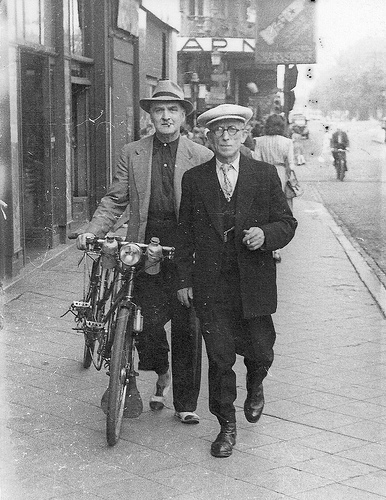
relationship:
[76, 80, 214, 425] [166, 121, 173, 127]
man smoking a cigar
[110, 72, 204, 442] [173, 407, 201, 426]
man wears shoe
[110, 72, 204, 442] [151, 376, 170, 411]
man wears shoe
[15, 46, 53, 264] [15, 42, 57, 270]
door with trim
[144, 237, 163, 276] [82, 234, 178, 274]
bottle on handlebars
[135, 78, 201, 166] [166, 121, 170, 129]
man with cigar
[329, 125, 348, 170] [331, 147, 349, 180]
man riding bicycle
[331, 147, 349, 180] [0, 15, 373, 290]
bicycle in distance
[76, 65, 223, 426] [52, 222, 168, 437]
man holding up bicucle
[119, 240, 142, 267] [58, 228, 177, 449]
headlight on bicycle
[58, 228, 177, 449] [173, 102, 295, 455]
bicycle by man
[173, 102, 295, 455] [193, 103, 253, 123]
man wearing hat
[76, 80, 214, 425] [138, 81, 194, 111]
man wearing hat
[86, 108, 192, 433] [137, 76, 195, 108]
man wearing hat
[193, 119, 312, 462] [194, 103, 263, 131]
man wearing hat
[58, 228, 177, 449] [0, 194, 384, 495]
bicycle on pavement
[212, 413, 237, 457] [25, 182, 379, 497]
boot on pavement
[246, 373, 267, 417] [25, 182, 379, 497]
boot on pavement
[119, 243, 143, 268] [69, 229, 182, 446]
headlight on bicycle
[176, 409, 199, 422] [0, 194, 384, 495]
shoes on pavement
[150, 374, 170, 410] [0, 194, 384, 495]
shoes on pavement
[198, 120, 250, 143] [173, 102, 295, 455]
glasses on man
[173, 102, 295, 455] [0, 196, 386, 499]
man on sidewalk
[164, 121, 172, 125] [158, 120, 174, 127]
cigarette in mouth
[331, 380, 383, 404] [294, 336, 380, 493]
tile on pavement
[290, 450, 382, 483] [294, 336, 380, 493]
tile on pavement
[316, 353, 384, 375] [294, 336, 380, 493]
tile on pavement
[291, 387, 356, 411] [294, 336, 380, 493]
tile on pavement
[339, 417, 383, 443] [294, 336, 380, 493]
tile on pavement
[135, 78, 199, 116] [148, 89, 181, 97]
fedora hat with black stripe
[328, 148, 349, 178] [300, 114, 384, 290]
bicycle down street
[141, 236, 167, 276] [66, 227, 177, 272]
metal bottle attached handle bars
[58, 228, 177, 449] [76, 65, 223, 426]
bicycle pushed by man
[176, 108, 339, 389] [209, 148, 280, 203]
man wearing tie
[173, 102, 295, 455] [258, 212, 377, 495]
man on sidewalk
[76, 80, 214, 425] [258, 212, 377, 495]
man on sidewalk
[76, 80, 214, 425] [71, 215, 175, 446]
man pushing bike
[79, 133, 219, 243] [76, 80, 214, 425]
jacket of man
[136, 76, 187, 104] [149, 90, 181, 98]
hat with band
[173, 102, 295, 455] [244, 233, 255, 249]
man holding cigarette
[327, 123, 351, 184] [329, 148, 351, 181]
person riding bicycle